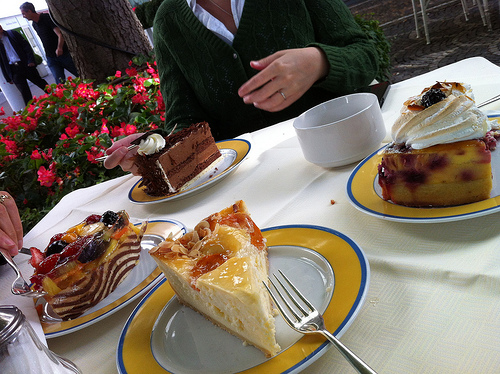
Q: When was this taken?
A: During a meal.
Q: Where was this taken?
A: At a table outside.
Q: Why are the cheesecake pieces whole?
A: They were just served.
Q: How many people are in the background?
A: Two.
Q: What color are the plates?
A: Yellow and blue.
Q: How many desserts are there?
A: Four.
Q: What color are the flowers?
A: Pink.